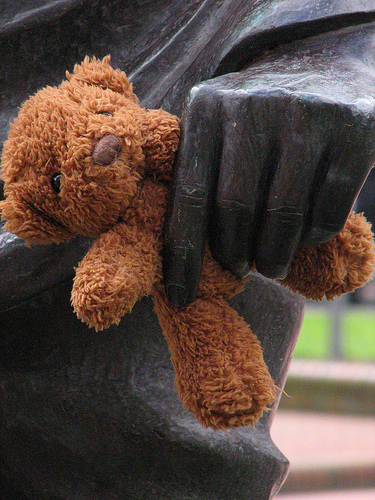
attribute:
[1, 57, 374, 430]
teddy bear — brown, stuffed, small, shaggy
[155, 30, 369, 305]
hand — black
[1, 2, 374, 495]
statue — male, black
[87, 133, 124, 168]
nose — brown, dark brown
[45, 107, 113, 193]
eyes — black, buttons, plastic, small, marble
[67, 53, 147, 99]
ear — curved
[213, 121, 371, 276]
fingers — curled